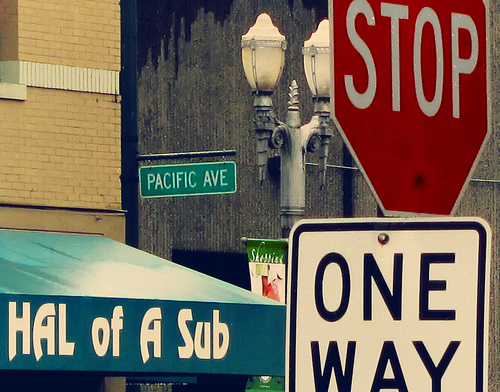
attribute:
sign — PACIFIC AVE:
[138, 165, 235, 195]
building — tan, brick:
[6, 3, 129, 235]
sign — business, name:
[3, 295, 293, 385]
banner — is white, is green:
[237, 234, 292, 390]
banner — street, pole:
[246, 238, 286, 304]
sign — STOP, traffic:
[327, 4, 494, 221]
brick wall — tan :
[0, 0, 125, 212]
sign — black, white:
[285, 216, 492, 390]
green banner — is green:
[199, 193, 332, 359]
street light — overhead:
[218, 10, 335, 203]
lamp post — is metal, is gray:
[252, 74, 331, 238]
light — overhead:
[238, 10, 289, 95]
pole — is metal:
[117, 0, 142, 247]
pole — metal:
[136, 147, 236, 160]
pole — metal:
[124, 152, 245, 163]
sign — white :
[135, 160, 242, 200]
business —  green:
[73, 93, 498, 390]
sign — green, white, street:
[108, 133, 285, 238]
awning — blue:
[1, 232, 258, 326]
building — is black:
[136, 1, 498, 390]